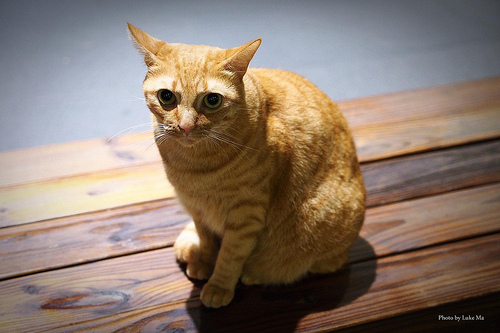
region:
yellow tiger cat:
[117, 17, 371, 309]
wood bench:
[2, 65, 498, 332]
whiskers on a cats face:
[102, 115, 277, 163]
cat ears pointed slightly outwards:
[119, 17, 273, 89]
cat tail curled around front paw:
[159, 212, 219, 283]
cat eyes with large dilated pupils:
[147, 82, 235, 112]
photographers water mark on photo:
[425, 300, 498, 330]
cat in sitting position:
[120, 15, 374, 313]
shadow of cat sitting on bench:
[145, 233, 450, 331]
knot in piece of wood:
[11, 272, 138, 316]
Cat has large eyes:
[139, 61, 256, 126]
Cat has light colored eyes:
[128, 72, 268, 163]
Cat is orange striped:
[166, 163, 293, 322]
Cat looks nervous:
[139, 60, 242, 126]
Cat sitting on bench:
[81, 237, 329, 328]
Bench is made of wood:
[36, 151, 146, 302]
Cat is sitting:
[261, 116, 392, 284]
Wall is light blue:
[58, 34, 113, 71]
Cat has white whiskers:
[110, 108, 196, 209]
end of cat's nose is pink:
[168, 118, 191, 152]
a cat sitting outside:
[28, 27, 413, 312]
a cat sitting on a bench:
[71, 6, 444, 319]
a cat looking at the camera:
[108, 13, 409, 313]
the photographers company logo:
[428, 303, 498, 328]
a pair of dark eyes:
[144, 79, 233, 120]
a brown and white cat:
[98, 19, 423, 327]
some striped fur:
[224, 184, 280, 261]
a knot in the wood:
[30, 264, 152, 331]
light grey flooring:
[16, 19, 110, 125]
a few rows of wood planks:
[22, 128, 141, 317]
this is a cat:
[125, 20, 372, 292]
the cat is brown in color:
[128, 23, 365, 285]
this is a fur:
[211, 130, 248, 157]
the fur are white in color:
[215, 134, 237, 146]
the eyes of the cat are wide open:
[156, 87, 228, 117]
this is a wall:
[19, 2, 105, 107]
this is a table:
[58, 169, 120, 226]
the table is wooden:
[80, 270, 104, 295]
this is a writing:
[436, 310, 488, 322]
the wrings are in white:
[434, 312, 495, 323]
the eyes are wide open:
[153, 88, 224, 110]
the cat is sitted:
[109, 42, 378, 310]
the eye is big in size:
[192, 87, 230, 116]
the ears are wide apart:
[99, 25, 281, 62]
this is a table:
[2, 139, 144, 329]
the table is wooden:
[0, 139, 147, 331]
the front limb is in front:
[197, 182, 269, 307]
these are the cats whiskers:
[105, 118, 163, 158]